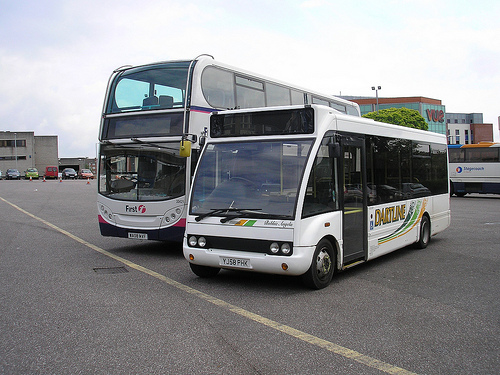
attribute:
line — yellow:
[179, 290, 356, 341]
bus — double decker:
[98, 43, 308, 273]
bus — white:
[183, 104, 451, 290]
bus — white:
[447, 141, 498, 201]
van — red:
[182, 96, 454, 291]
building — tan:
[1, 127, 61, 177]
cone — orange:
[83, 173, 92, 187]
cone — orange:
[58, 176, 63, 183]